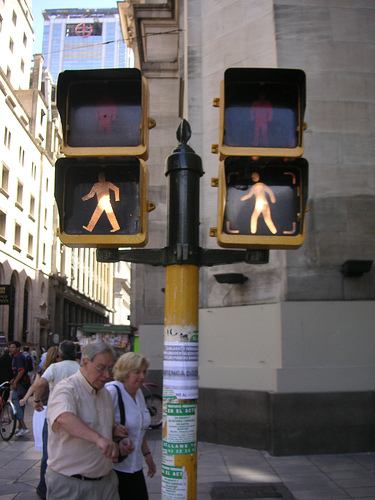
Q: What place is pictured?
A: It is a city.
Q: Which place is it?
A: It is a city.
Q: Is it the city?
A: Yes, it is the city.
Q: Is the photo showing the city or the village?
A: It is showing the city.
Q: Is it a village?
A: No, it is a city.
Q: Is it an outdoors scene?
A: Yes, it is outdoors.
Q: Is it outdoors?
A: Yes, it is outdoors.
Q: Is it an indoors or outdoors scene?
A: It is outdoors.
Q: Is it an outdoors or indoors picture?
A: It is outdoors.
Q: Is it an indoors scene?
A: No, it is outdoors.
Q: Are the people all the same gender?
A: No, they are both male and female.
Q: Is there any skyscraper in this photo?
A: Yes, there is a skyscraper.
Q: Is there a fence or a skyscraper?
A: Yes, there is a skyscraper.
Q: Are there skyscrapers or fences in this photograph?
A: Yes, there is a skyscraper.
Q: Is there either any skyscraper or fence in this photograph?
A: Yes, there is a skyscraper.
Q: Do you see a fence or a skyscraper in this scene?
A: Yes, there is a skyscraper.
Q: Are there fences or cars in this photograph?
A: No, there are no fences or cars.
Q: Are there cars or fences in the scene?
A: No, there are no fences or cars.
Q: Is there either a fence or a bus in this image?
A: No, there are no fences or buses.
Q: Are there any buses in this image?
A: No, there are no buses.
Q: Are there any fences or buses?
A: No, there are no buses or fences.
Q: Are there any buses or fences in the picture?
A: No, there are no buses or fences.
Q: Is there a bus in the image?
A: No, there are no buses.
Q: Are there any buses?
A: No, there are no buses.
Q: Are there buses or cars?
A: No, there are no buses or cars.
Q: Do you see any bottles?
A: No, there are no bottles.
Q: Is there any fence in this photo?
A: No, there are no fences.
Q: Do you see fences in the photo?
A: No, there are no fences.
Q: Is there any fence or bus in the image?
A: No, there are no fences or buses.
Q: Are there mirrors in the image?
A: No, there are no mirrors.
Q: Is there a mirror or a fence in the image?
A: No, there are no mirrors or fences.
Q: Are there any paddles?
A: No, there are no paddles.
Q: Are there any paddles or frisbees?
A: No, there are no paddles or frisbees.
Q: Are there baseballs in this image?
A: No, there are no baseballs.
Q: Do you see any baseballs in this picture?
A: No, there are no baseballs.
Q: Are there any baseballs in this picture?
A: No, there are no baseballs.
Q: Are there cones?
A: No, there are no cones.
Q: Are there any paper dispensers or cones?
A: No, there are no cones or paper dispensers.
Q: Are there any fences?
A: No, there are no fences.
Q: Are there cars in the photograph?
A: No, there are no cars.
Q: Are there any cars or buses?
A: No, there are no cars or buses.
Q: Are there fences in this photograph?
A: No, there are no fences.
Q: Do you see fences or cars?
A: No, there are no fences or cars.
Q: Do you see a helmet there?
A: No, there are no helmets.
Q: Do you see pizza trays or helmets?
A: No, there are no helmets or pizza trays.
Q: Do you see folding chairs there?
A: No, there are no folding chairs.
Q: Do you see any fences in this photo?
A: No, there are no fences.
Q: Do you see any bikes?
A: Yes, there is a bike.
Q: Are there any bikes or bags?
A: Yes, there is a bike.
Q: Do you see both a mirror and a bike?
A: No, there is a bike but no mirrors.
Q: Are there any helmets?
A: No, there are no helmets.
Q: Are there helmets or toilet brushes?
A: No, there are no helmets or toilet brushes.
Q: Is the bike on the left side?
A: Yes, the bike is on the left of the image.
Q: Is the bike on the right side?
A: No, the bike is on the left of the image.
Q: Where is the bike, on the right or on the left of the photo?
A: The bike is on the left of the image.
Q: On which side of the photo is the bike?
A: The bike is on the left of the image.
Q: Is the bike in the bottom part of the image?
A: Yes, the bike is in the bottom of the image.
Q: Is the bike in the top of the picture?
A: No, the bike is in the bottom of the image.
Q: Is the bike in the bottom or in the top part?
A: The bike is in the bottom of the image.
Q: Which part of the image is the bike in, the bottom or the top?
A: The bike is in the bottom of the image.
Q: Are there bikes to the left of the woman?
A: Yes, there is a bike to the left of the woman.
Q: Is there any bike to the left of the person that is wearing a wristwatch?
A: Yes, there is a bike to the left of the woman.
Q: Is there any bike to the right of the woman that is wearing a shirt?
A: No, the bike is to the left of the woman.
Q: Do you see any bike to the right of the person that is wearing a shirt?
A: No, the bike is to the left of the woman.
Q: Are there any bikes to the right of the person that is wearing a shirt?
A: No, the bike is to the left of the woman.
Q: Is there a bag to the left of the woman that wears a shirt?
A: No, there is a bike to the left of the woman.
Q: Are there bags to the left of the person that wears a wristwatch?
A: No, there is a bike to the left of the woman.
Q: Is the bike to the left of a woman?
A: Yes, the bike is to the left of a woman.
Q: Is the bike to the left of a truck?
A: No, the bike is to the left of a woman.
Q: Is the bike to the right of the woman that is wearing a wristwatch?
A: No, the bike is to the left of the woman.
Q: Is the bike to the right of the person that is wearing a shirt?
A: No, the bike is to the left of the woman.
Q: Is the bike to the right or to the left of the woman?
A: The bike is to the left of the woman.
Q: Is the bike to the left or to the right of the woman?
A: The bike is to the left of the woman.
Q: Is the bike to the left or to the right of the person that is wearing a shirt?
A: The bike is to the left of the woman.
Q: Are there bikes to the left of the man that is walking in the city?
A: Yes, there is a bike to the left of the man.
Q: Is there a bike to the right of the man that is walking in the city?
A: No, the bike is to the left of the man.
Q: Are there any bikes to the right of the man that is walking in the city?
A: No, the bike is to the left of the man.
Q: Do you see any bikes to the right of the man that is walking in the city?
A: No, the bike is to the left of the man.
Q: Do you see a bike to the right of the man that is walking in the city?
A: No, the bike is to the left of the man.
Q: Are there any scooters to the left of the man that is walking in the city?
A: No, there is a bike to the left of the man.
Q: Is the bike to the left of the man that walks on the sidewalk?
A: Yes, the bike is to the left of the man.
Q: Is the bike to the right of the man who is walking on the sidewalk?
A: No, the bike is to the left of the man.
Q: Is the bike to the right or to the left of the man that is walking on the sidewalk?
A: The bike is to the left of the man.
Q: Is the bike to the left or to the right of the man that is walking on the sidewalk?
A: The bike is to the left of the man.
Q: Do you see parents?
A: No, there are no parents.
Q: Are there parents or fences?
A: No, there are no parents or fences.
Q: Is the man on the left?
A: Yes, the man is on the left of the image.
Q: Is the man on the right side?
A: No, the man is on the left of the image.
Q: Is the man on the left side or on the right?
A: The man is on the left of the image.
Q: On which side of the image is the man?
A: The man is on the left of the image.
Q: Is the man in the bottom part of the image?
A: Yes, the man is in the bottom of the image.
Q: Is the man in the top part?
A: No, the man is in the bottom of the image.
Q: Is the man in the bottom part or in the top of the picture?
A: The man is in the bottom of the image.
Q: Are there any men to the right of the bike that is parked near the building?
A: Yes, there is a man to the right of the bike.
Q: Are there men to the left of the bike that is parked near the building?
A: No, the man is to the right of the bike.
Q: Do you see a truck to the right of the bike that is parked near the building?
A: No, there is a man to the right of the bike.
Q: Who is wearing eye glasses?
A: The man is wearing eye glasses.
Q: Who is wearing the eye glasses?
A: The man is wearing eye glasses.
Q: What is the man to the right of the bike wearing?
A: The man is wearing eyeglasses.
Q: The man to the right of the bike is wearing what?
A: The man is wearing eyeglasses.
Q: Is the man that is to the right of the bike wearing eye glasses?
A: Yes, the man is wearing eye glasses.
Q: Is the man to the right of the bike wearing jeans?
A: No, the man is wearing eye glasses.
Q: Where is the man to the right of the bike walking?
A: The man is walking in the city.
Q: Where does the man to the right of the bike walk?
A: The man walks on the side walk.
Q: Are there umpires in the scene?
A: No, there are no umpires.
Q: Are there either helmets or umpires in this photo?
A: No, there are no umpires or helmets.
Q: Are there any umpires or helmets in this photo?
A: No, there are no umpires or helmets.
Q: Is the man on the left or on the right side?
A: The man is on the left of the image.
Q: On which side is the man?
A: The man is on the left of the image.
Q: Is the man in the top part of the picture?
A: No, the man is in the bottom of the image.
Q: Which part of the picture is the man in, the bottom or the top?
A: The man is in the bottom of the image.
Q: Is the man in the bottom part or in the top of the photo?
A: The man is in the bottom of the image.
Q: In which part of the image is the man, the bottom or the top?
A: The man is in the bottom of the image.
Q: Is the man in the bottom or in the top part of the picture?
A: The man is in the bottom of the image.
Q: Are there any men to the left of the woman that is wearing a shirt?
A: Yes, there is a man to the left of the woman.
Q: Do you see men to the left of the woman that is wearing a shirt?
A: Yes, there is a man to the left of the woman.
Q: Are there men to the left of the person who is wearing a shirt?
A: Yes, there is a man to the left of the woman.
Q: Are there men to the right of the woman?
A: No, the man is to the left of the woman.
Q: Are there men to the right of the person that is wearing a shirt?
A: No, the man is to the left of the woman.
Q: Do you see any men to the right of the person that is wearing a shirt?
A: No, the man is to the left of the woman.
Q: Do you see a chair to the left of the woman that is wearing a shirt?
A: No, there is a man to the left of the woman.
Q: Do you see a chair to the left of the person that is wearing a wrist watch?
A: No, there is a man to the left of the woman.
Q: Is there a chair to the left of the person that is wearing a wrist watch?
A: No, there is a man to the left of the woman.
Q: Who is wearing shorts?
A: The man is wearing shorts.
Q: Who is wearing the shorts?
A: The man is wearing shorts.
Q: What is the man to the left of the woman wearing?
A: The man is wearing shorts.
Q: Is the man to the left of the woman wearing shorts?
A: Yes, the man is wearing shorts.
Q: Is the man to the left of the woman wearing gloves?
A: No, the man is wearing shorts.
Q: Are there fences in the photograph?
A: No, there are no fences.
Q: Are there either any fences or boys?
A: No, there are no fences or boys.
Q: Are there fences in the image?
A: No, there are no fences.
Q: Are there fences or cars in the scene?
A: No, there are no fences or cars.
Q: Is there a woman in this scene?
A: Yes, there is a woman.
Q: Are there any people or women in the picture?
A: Yes, there is a woman.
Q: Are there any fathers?
A: No, there are no fathers.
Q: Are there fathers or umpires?
A: No, there are no fathers or umpires.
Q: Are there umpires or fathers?
A: No, there are no fathers or umpires.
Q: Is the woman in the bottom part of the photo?
A: Yes, the woman is in the bottom of the image.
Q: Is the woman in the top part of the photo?
A: No, the woman is in the bottom of the image.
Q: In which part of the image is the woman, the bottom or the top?
A: The woman is in the bottom of the image.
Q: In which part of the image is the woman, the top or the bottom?
A: The woman is in the bottom of the image.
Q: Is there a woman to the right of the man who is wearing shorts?
A: Yes, there is a woman to the right of the man.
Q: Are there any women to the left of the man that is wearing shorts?
A: No, the woman is to the right of the man.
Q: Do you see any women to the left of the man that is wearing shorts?
A: No, the woman is to the right of the man.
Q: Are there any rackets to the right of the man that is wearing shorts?
A: No, there is a woman to the right of the man.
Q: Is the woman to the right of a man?
A: Yes, the woman is to the right of a man.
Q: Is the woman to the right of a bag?
A: No, the woman is to the right of a man.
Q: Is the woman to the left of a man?
A: No, the woman is to the right of a man.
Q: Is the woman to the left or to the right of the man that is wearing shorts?
A: The woman is to the right of the man.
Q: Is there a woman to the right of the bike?
A: Yes, there is a woman to the right of the bike.